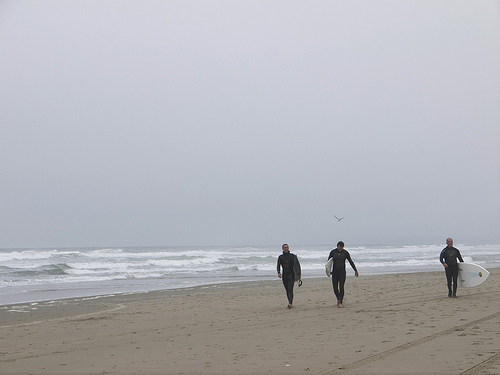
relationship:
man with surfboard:
[276, 244, 304, 307] [292, 257, 298, 282]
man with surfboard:
[327, 240, 360, 307] [325, 260, 332, 278]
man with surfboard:
[439, 235, 463, 299] [455, 259, 489, 288]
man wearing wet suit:
[276, 244, 304, 307] [275, 253, 297, 303]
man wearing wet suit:
[327, 240, 360, 307] [330, 247, 354, 301]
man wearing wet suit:
[439, 235, 463, 299] [441, 251, 465, 293]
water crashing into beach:
[0, 244, 495, 310] [1, 269, 500, 372]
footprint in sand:
[325, 358, 338, 366] [8, 273, 496, 367]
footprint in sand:
[355, 348, 363, 356] [8, 273, 496, 367]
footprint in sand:
[381, 337, 394, 346] [8, 273, 496, 367]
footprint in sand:
[407, 328, 415, 339] [8, 273, 496, 367]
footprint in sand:
[427, 316, 438, 323] [8, 273, 496, 367]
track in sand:
[334, 312, 498, 374] [8, 273, 496, 367]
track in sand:
[457, 348, 498, 375] [8, 273, 496, 367]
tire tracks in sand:
[331, 301, 498, 373] [144, 306, 282, 371]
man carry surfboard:
[439, 235, 463, 299] [458, 259, 491, 292]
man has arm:
[439, 235, 463, 299] [436, 248, 450, 270]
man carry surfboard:
[327, 240, 360, 307] [324, 255, 335, 275]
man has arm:
[327, 240, 360, 307] [347, 250, 363, 276]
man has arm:
[276, 244, 304, 307] [277, 253, 282, 279]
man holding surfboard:
[276, 244, 304, 307] [292, 265, 311, 282]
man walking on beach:
[276, 244, 304, 307] [0, 294, 491, 365]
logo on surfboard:
[477, 268, 483, 278] [454, 260, 487, 286]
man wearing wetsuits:
[276, 244, 304, 307] [276, 252, 300, 303]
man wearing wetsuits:
[327, 240, 360, 307] [324, 248, 358, 300]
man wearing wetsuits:
[439, 235, 463, 299] [435, 246, 468, 291]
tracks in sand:
[327, 310, 499, 373] [8, 273, 496, 367]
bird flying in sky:
[328, 211, 349, 225] [32, 10, 488, 259]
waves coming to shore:
[2, 242, 482, 291] [0, 264, 497, 371]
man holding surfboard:
[439, 235, 463, 299] [455, 262, 490, 290]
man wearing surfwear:
[439, 235, 463, 299] [256, 234, 487, 314]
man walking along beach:
[439, 235, 463, 299] [0, 253, 500, 373]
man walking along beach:
[327, 240, 360, 307] [0, 253, 500, 373]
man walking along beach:
[276, 244, 304, 307] [0, 253, 500, 373]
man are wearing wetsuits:
[439, 235, 463, 299] [278, 247, 463, 301]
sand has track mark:
[8, 273, 496, 367] [458, 350, 498, 372]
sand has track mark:
[8, 273, 496, 367] [327, 306, 494, 373]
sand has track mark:
[8, 273, 496, 367] [355, 281, 488, 314]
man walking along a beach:
[265, 237, 308, 307] [0, 253, 500, 373]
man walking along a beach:
[313, 230, 370, 307] [0, 253, 500, 373]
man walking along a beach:
[429, 228, 471, 299] [0, 253, 500, 373]